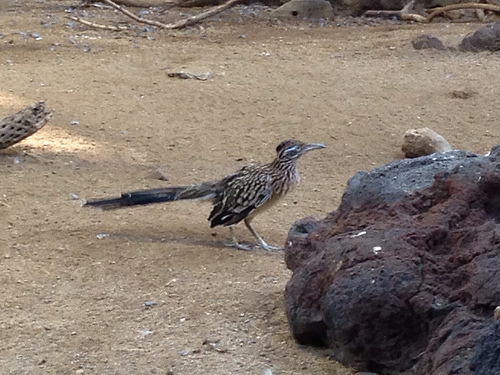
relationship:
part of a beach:
[40, 183, 132, 316] [0, 0, 499, 373]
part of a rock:
[281, 238, 354, 314] [292, 135, 494, 357]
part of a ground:
[0, 223, 129, 317] [6, 30, 488, 366]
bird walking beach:
[84, 140, 324, 252] [0, 0, 499, 373]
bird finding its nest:
[79, 133, 331, 262] [82, 58, 238, 184]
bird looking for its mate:
[84, 140, 324, 252] [124, 113, 304, 283]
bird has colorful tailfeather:
[84, 140, 324, 252] [86, 184, 216, 205]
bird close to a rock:
[84, 140, 324, 252] [259, 220, 377, 374]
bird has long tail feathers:
[84, 140, 324, 252] [84, 172, 209, 232]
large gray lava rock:
[282, 164, 495, 373] [240, 109, 499, 337]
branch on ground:
[68, 1, 290, 36] [6, 30, 488, 366]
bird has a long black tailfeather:
[79, 133, 331, 262] [79, 177, 222, 212]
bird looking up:
[84, 140, 324, 252] [319, 67, 416, 181]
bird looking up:
[84, 140, 324, 252] [293, 170, 377, 257]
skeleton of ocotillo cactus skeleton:
[0, 102, 50, 148] [0, 95, 50, 153]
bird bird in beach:
[84, 140, 324, 252] [0, 0, 499, 373]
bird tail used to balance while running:
[84, 140, 324, 252] [157, 210, 254, 346]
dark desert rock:
[195, 186, 448, 375] [283, 151, 498, 373]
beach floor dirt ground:
[0, 0, 499, 373] [6, 30, 488, 366]